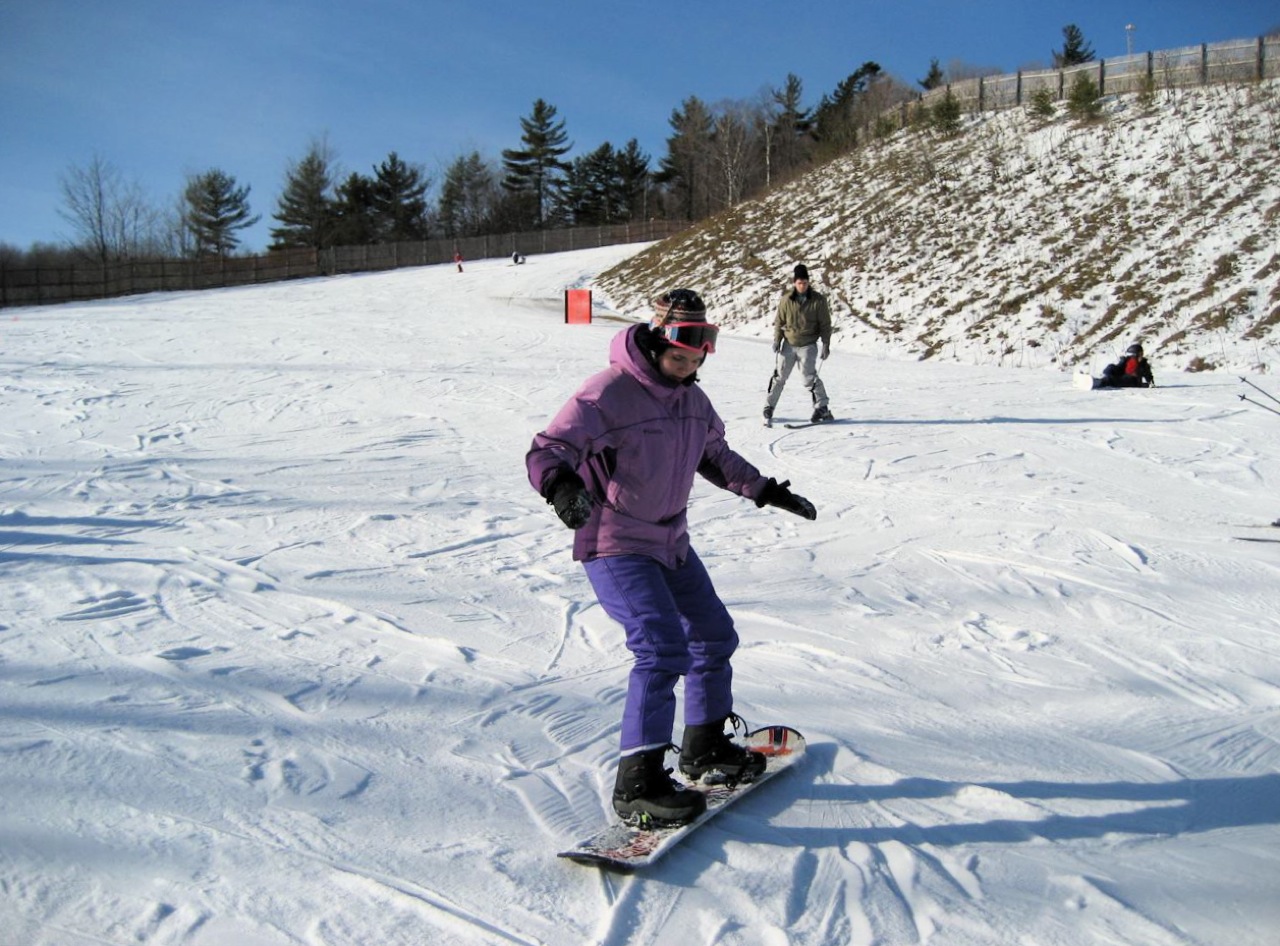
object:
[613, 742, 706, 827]
shoe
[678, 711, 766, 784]
shoe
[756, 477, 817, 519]
glove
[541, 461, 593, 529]
glove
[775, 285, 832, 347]
jacket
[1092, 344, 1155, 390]
person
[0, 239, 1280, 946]
snow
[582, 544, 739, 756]
pants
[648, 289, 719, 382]
head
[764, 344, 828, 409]
pants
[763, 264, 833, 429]
man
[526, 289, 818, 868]
boarder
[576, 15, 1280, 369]
hill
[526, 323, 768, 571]
coat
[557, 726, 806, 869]
snowboard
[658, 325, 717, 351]
goggles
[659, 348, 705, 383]
face